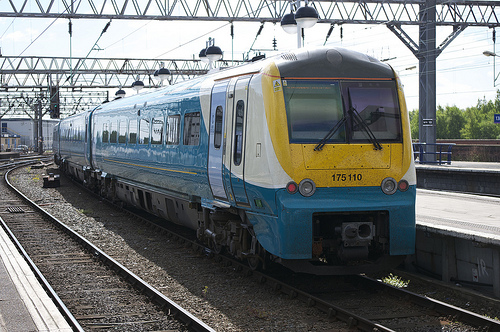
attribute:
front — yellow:
[252, 50, 409, 266]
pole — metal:
[394, 9, 485, 194]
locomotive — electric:
[50, 14, 445, 301]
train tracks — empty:
[0, 161, 221, 330]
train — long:
[87, 49, 424, 271]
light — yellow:
[398, 176, 410, 197]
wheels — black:
[166, 207, 266, 279]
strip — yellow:
[110, 159, 199, 180]